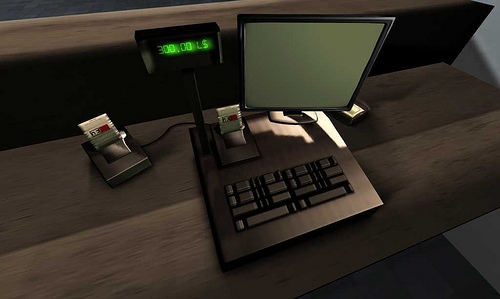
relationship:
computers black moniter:
[193, 111, 384, 274] [234, 12, 392, 112]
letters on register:
[155, 37, 210, 60] [76, 14, 397, 273]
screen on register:
[242, 23, 349, 107] [76, 14, 397, 273]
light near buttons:
[257, 112, 346, 152] [222, 155, 356, 234]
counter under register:
[380, 60, 499, 229] [76, 14, 397, 273]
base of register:
[194, 112, 385, 272] [76, 14, 397, 273]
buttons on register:
[222, 155, 356, 234] [76, 14, 397, 273]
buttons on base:
[222, 155, 356, 234] [194, 112, 385, 272]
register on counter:
[76, 14, 397, 273] [380, 60, 499, 229]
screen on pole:
[146, 34, 218, 66] [175, 68, 215, 153]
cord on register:
[137, 118, 190, 147] [76, 14, 397, 273]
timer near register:
[75, 111, 155, 195] [76, 14, 397, 273]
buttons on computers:
[222, 155, 356, 234] [193, 111, 384, 274]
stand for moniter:
[267, 109, 318, 126] [234, 12, 392, 112]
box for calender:
[84, 143, 149, 192] [78, 113, 122, 153]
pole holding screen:
[175, 68, 215, 153] [146, 34, 218, 66]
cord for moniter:
[137, 118, 190, 147] [234, 12, 392, 112]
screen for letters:
[146, 34, 218, 66] [155, 37, 210, 60]